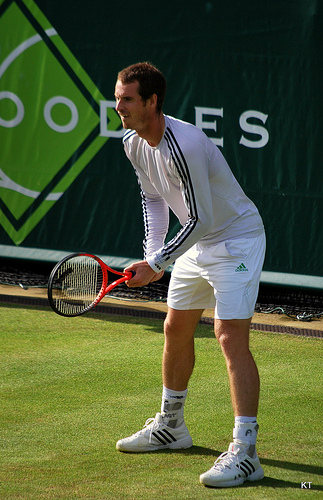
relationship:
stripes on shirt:
[141, 133, 214, 268] [112, 121, 255, 238]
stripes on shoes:
[126, 422, 258, 475] [118, 410, 265, 481]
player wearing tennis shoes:
[114, 59, 271, 489] [115, 412, 264, 486]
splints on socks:
[160, 383, 260, 426] [148, 385, 279, 460]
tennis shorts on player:
[155, 251, 260, 317] [104, 66, 201, 164]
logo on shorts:
[229, 258, 256, 275] [162, 234, 268, 328]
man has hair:
[113, 60, 267, 490] [114, 59, 177, 119]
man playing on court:
[113, 60, 267, 490] [5, 296, 315, 499]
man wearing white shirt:
[111, 57, 268, 489] [118, 112, 267, 272]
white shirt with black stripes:
[118, 112, 267, 272] [158, 125, 198, 261]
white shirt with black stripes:
[118, 112, 267, 272] [119, 127, 150, 260]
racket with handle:
[45, 251, 138, 317] [86, 255, 145, 300]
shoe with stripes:
[194, 438, 277, 495] [157, 133, 207, 231]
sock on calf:
[225, 419, 257, 445] [222, 355, 271, 420]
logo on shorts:
[236, 261, 252, 273] [161, 228, 269, 321]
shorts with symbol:
[177, 232, 272, 311] [235, 255, 250, 276]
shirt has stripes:
[123, 114, 265, 268] [183, 225, 192, 246]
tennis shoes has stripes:
[200, 445, 278, 488] [245, 446, 250, 482]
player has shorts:
[114, 59, 271, 489] [165, 230, 266, 317]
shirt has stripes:
[114, 117, 265, 267] [167, 224, 195, 255]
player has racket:
[114, 59, 271, 489] [45, 251, 138, 317]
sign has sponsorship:
[9, 26, 121, 179] [9, 91, 88, 125]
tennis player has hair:
[111, 62, 266, 487] [116, 62, 165, 121]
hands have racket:
[115, 250, 163, 289] [38, 236, 167, 314]